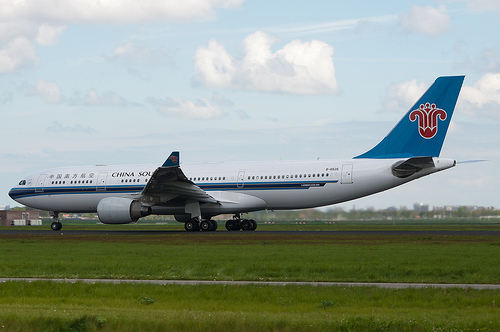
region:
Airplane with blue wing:
[7, 68, 472, 233]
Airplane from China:
[7, 72, 484, 232]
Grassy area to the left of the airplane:
[0, 233, 498, 280]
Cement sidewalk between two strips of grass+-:
[0, 269, 498, 294]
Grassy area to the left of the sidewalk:
[0, 279, 497, 329]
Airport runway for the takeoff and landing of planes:
[0, 221, 499, 245]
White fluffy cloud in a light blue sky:
[178, 26, 340, 106]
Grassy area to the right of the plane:
[0, 213, 497, 226]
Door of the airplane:
[93, 166, 109, 195]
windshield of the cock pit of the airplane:
[17, 175, 25, 190]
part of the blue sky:
[152, 51, 311, 142]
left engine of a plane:
[92, 194, 144, 220]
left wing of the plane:
[131, 160, 213, 192]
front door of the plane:
[33, 173, 46, 195]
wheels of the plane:
[208, 208, 257, 236]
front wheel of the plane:
[49, 216, 61, 233]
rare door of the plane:
[339, 158, 360, 188]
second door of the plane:
[88, 164, 120, 192]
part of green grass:
[203, 270, 310, 321]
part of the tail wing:
[388, 74, 435, 146]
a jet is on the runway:
[5, 72, 487, 245]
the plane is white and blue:
[5, 71, 485, 246]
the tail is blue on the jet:
[350, 75, 463, 156]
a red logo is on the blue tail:
[352, 73, 462, 155]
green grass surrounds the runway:
[0, 220, 495, 328]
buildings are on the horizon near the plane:
[0, 203, 175, 229]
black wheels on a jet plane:
[45, 216, 256, 232]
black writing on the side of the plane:
[41, 166, 152, 179]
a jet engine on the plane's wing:
[92, 148, 262, 228]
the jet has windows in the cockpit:
[8, 170, 36, 212]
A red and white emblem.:
[410, 102, 446, 142]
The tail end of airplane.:
[352, 75, 484, 180]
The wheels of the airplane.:
[46, 215, 256, 225]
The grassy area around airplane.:
[0, 236, 490, 326]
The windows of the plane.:
[50, 175, 140, 180]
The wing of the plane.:
[96, 155, 266, 225]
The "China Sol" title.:
[105, 165, 150, 177]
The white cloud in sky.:
[190, 40, 345, 85]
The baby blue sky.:
[252, 0, 337, 25]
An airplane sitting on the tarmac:
[0, 0, 498, 330]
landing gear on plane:
[180, 215, 266, 235]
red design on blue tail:
[407, 95, 453, 147]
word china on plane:
[100, 168, 140, 181]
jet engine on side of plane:
[87, 191, 148, 232]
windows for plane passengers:
[256, 168, 332, 181]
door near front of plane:
[30, 166, 52, 197]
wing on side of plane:
[135, 152, 246, 223]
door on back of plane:
[328, 159, 360, 191]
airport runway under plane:
[266, 221, 421, 237]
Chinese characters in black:
[50, 168, 96, 183]